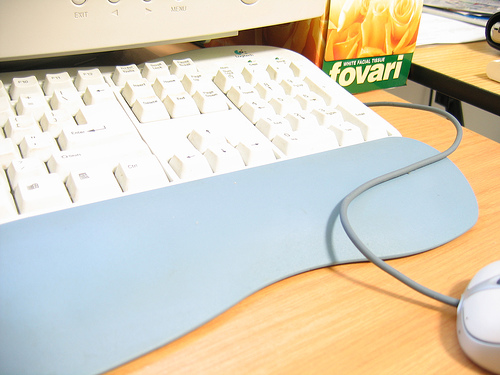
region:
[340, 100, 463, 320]
Mouse cord on a keyboard.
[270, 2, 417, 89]
Box of food next to a monitor.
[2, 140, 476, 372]
Wrist pad for a keyboard.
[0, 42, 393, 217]
White computer keyboard on table.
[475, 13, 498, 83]
Computer camera sitting on table.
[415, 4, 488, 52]
Notebook sitting on a table.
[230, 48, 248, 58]
Keyboard brand logo on the side.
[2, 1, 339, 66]
Computer monitor sitting on table.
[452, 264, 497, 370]
White computer mouse on table.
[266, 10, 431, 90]
Yellow, green, and white box of snacks.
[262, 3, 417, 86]
Box of fovari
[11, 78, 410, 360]
White slanted keyboard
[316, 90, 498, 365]
Computer mouse on a wire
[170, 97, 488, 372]
Light tan fake wood desk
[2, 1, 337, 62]
computer monitor on desk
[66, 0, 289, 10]
small buttons on computer monitor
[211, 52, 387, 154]
number pad on keyboard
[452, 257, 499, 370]
white computer mouse on desk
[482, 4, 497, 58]
black coffee mug handle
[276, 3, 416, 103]
fovari snack box is next to keyboard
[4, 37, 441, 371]
white and blue computer keyboard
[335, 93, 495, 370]
white mouse with grey cord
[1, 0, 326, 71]
edge of white desktop computer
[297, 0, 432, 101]
green and white box with food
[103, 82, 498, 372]
light oak colored desk top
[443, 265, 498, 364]
white mouse on wooden desk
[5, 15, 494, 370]
indoor room office scene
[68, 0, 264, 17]
small round buttons on white computer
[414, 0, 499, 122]
adjacent wooden desk with black trim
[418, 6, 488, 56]
white papers on adjacent desk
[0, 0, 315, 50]
computer monitor button labels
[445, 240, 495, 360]
white computer mouse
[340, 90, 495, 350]
computer mouse cord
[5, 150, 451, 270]
blue keyboard wrist pad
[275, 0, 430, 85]
box of fovari with photo and green background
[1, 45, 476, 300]
white computer keyboard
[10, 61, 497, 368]
wooden desk top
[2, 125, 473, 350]
blue keyboard wrist rest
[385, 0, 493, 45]
white paper on desk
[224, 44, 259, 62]
logitech logo on keyboard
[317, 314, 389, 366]
wooden part of a desktop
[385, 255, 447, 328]
part of a mouse wire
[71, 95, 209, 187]
white part of a keyboard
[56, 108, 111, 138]
part of a enter button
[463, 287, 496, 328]
part of a mouse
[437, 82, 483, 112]
edge of a desktop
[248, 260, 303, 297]
edge of a keyboard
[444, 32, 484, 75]
surface of another desktop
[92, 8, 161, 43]
part of a monitor